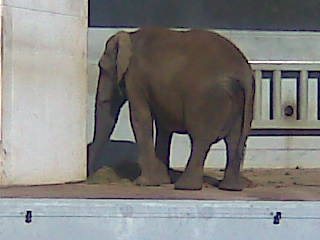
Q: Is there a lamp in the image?
A: No, there are no lamps.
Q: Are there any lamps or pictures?
A: No, there are no lamps or pictures.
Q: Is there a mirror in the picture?
A: No, there are no mirrors.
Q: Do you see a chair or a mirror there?
A: No, there are no mirrors or chairs.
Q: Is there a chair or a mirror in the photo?
A: No, there are no mirrors or chairs.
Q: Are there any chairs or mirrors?
A: No, there are no mirrors or chairs.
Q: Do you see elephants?
A: Yes, there is an elephant.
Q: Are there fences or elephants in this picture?
A: Yes, there is an elephant.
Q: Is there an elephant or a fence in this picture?
A: Yes, there is an elephant.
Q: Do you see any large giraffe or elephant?
A: Yes, there is a large elephant.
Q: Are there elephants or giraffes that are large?
A: Yes, the elephant is large.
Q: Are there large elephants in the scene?
A: Yes, there is a large elephant.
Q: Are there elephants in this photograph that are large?
A: Yes, there is an elephant that is large.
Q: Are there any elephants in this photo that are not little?
A: Yes, there is a large elephant.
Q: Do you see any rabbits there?
A: No, there are no rabbits.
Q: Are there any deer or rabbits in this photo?
A: No, there are no rabbits or deer.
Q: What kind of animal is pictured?
A: The animal is an elephant.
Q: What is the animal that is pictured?
A: The animal is an elephant.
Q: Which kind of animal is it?
A: The animal is an elephant.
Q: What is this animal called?
A: This is an elephant.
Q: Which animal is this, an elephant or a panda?
A: This is an elephant.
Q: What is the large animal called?
A: The animal is an elephant.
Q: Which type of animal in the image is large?
A: The animal is an elephant.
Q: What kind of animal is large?
A: The animal is an elephant.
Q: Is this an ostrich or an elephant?
A: This is an elephant.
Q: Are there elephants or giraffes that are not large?
A: No, there is an elephant but it is large.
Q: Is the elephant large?
A: Yes, the elephant is large.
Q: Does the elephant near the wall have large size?
A: Yes, the elephant is large.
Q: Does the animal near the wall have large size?
A: Yes, the elephant is large.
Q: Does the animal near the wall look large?
A: Yes, the elephant is large.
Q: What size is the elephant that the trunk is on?
A: The elephant is large.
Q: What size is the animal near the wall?
A: The elephant is large.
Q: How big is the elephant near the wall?
A: The elephant is large.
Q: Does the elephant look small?
A: No, the elephant is large.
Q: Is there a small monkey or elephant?
A: No, there is an elephant but it is large.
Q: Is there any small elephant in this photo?
A: No, there is an elephant but it is large.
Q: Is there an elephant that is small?
A: No, there is an elephant but it is large.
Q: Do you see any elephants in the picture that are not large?
A: No, there is an elephant but it is large.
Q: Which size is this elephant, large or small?
A: The elephant is large.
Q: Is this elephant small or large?
A: The elephant is large.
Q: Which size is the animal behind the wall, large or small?
A: The elephant is large.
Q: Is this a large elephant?
A: Yes, this is a large elephant.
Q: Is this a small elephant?
A: No, this is a large elephant.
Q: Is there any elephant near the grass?
A: Yes, there is an elephant near the grass.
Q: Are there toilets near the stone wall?
A: No, there is an elephant near the wall.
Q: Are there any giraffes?
A: No, there are no giraffes.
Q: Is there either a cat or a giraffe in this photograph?
A: No, there are no giraffes or cats.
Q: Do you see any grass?
A: Yes, there is grass.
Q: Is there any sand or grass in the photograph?
A: Yes, there is grass.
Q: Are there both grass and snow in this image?
A: No, there is grass but no snow.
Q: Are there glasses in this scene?
A: No, there are no glasses.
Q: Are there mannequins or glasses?
A: No, there are no glasses or mannequins.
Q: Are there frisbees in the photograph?
A: No, there are no frisbees.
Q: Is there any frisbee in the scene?
A: No, there are no frisbees.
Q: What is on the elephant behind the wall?
A: The trunk is on the elephant.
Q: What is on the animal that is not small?
A: The trunk is on the elephant.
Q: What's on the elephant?
A: The trunk is on the elephant.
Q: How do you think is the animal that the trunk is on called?
A: The animal is an elephant.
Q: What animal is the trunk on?
A: The trunk is on the elephant.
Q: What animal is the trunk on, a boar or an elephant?
A: The trunk is on an elephant.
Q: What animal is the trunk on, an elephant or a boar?
A: The trunk is on an elephant.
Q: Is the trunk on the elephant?
A: Yes, the trunk is on the elephant.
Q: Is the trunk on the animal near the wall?
A: Yes, the trunk is on the elephant.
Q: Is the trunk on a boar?
A: No, the trunk is on the elephant.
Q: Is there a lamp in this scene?
A: No, there are no lamps.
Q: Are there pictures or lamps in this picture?
A: No, there are no lamps or pictures.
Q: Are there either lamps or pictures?
A: No, there are no lamps or pictures.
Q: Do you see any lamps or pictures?
A: No, there are no lamps or pictures.